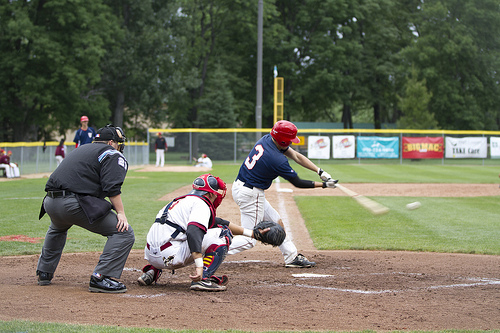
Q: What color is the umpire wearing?
A: Black.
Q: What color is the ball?
A: White.